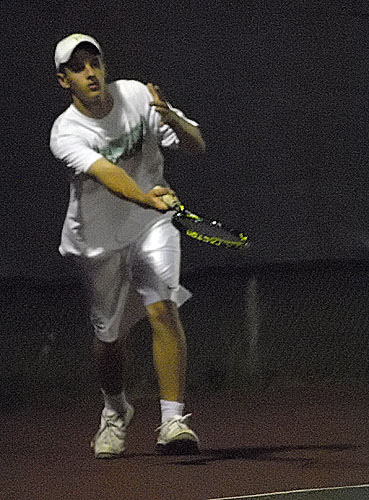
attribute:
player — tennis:
[54, 19, 225, 496]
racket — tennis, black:
[148, 174, 239, 248]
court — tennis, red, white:
[17, 291, 359, 498]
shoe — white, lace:
[90, 402, 215, 476]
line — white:
[313, 466, 350, 496]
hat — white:
[42, 20, 104, 72]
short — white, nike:
[82, 216, 198, 329]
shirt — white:
[49, 56, 209, 275]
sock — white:
[155, 386, 206, 419]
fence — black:
[269, 249, 320, 336]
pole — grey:
[231, 269, 283, 412]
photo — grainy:
[23, 17, 343, 476]